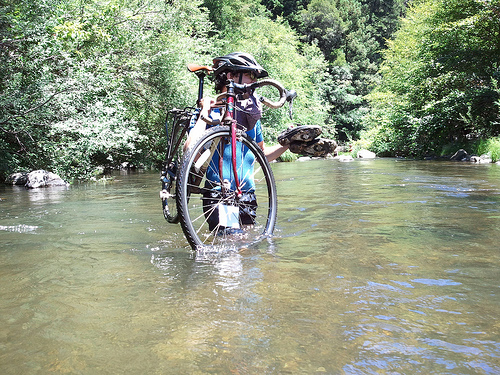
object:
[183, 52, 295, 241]
biker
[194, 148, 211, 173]
reflector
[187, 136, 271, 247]
spokes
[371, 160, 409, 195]
ground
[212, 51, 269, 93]
grey helmet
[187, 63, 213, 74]
bike seat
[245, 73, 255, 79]
glasses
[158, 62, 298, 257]
bicycle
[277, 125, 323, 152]
shoes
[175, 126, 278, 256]
bike wheels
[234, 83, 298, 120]
handle bars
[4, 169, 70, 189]
rocks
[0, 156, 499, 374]
river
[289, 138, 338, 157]
shoes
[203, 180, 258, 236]
pants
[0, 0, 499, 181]
forest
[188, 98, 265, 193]
shirt